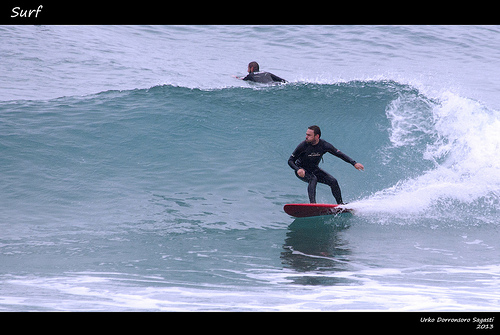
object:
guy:
[234, 60, 284, 89]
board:
[283, 204, 353, 217]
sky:
[322, 0, 410, 30]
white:
[389, 89, 461, 165]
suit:
[276, 121, 367, 210]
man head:
[305, 125, 320, 143]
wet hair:
[308, 126, 321, 136]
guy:
[291, 120, 358, 204]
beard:
[305, 139, 317, 144]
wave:
[325, 62, 487, 252]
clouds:
[94, 28, 218, 85]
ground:
[386, 166, 418, 227]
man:
[276, 112, 348, 217]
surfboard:
[277, 197, 354, 219]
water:
[4, 21, 499, 311]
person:
[254, 119, 376, 224]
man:
[280, 125, 359, 205]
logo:
[418, 315, 496, 333]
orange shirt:
[64, 109, 176, 201]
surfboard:
[278, 206, 357, 215]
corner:
[417, 300, 484, 327]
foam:
[324, 71, 484, 221]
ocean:
[8, 37, 484, 301]